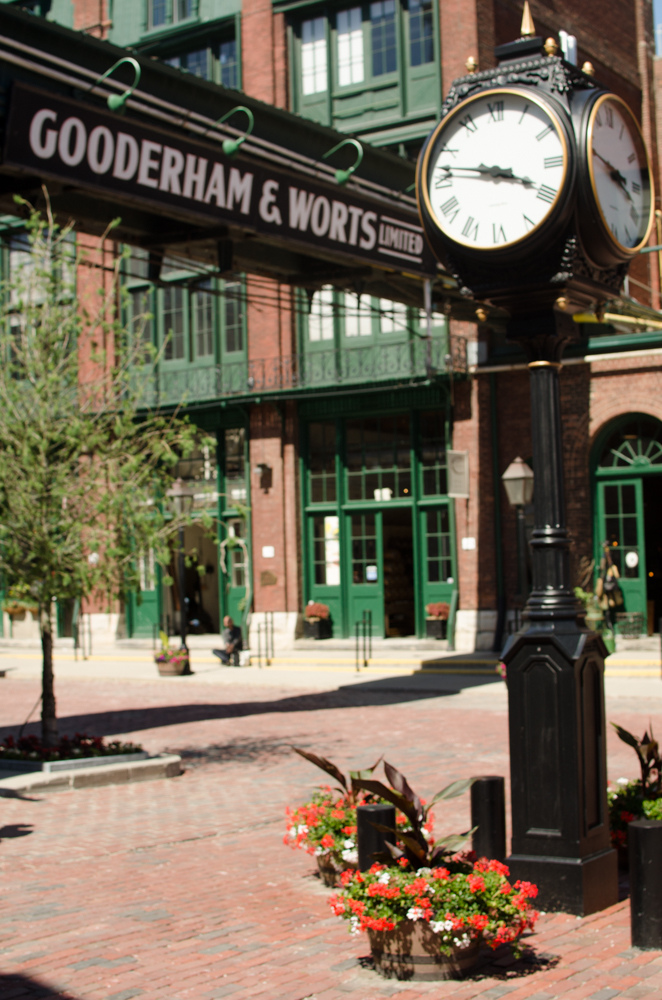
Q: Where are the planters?
A: On the street.